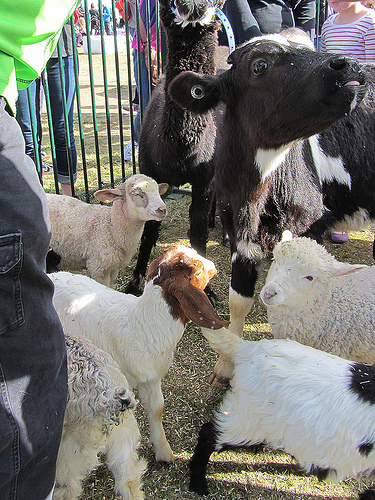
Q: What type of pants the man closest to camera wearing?
A: Cargo.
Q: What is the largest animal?
A: Cow.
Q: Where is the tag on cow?
A: Ear.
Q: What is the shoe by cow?
A: Purple.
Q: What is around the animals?
A: Fence.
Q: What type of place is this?
A: Petting zoo.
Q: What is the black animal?
A: Cow.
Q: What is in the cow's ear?
A: Tag.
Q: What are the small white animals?
A: Sheep.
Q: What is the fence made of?
A: Metal.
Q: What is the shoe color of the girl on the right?
A: Purple.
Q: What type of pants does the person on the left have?
A: Denim.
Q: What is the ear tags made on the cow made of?
A: Metal.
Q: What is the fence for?
A: Enclose animals.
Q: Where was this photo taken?
A: At a petting zoo.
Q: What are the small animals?
A: Lamb.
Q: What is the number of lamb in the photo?
A: Four.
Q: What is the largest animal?
A: A cow.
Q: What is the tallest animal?
A: A llama.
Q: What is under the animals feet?
A: Hay.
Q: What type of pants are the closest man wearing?
A: Jeans.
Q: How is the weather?
A: Sunny.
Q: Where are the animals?
A: In a pen.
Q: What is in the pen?
A: Goats.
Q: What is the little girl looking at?
A: Goats.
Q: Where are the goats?
A: In a pen.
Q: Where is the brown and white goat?
A: In the pen.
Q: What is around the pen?
A: People looking at the goats.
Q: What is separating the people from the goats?
A: A metal green fence.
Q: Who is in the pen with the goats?
A: A little girl.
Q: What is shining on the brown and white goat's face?
A: The sun.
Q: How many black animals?
A: Two.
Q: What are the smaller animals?
A: Sheep & goats.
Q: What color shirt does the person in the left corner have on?
A: Green.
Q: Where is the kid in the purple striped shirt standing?
A: Behind the cow.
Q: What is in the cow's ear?
A: Tag.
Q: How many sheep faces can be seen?
A: Two.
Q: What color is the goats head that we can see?
A: Brown and white.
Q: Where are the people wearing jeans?
A: Behind the fence.